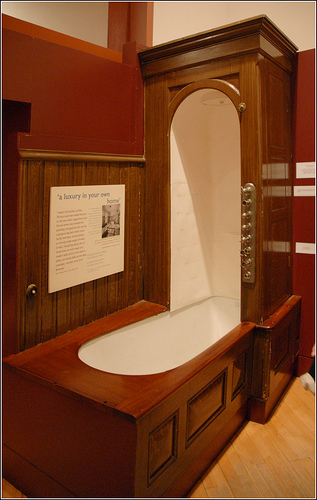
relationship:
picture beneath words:
[101, 199, 124, 242] [50, 182, 121, 204]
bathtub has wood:
[73, 305, 256, 383] [8, 294, 258, 419]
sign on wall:
[43, 178, 136, 297] [10, 146, 150, 341]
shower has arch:
[150, 66, 250, 329] [163, 76, 249, 134]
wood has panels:
[130, 307, 312, 493] [144, 406, 180, 485]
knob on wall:
[23, 279, 43, 306] [10, 146, 150, 341]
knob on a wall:
[23, 279, 43, 306] [10, 146, 150, 341]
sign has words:
[43, 178, 136, 297] [50, 182, 121, 204]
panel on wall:
[22, 153, 42, 351] [10, 146, 150, 341]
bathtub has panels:
[73, 305, 256, 383] [144, 406, 180, 485]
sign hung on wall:
[43, 178, 136, 297] [10, 146, 150, 341]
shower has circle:
[150, 66, 250, 329] [197, 93, 235, 116]